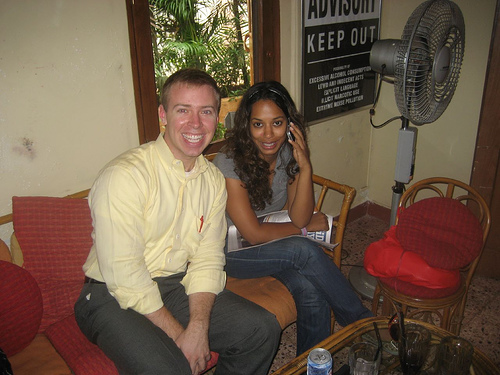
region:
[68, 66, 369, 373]
A man and a woman on a cell phone sitting on bamboo bench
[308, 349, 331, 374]
A can on the table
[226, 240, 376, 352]
The woman is wearing blue pants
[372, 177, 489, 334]
A chair by the couch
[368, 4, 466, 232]
A fan near the chair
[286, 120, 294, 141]
The woman is using a cell phone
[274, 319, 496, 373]
A table near the couch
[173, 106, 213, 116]
The eyes of the man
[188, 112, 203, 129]
The nose of the man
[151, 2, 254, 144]
A window behind the people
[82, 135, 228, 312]
The man is wearing a yellow shirt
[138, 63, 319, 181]
face of the person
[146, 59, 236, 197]
face of the boy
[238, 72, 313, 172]
face of the girl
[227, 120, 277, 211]
curley hairs of the girl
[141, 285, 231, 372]
hand of the man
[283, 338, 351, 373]
a bottle in the table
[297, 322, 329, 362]
a part of bottle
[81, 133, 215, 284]
a man wearing shirt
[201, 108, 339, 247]
a woman wearing shirt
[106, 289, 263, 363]
a man wearing pants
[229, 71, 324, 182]
the girl is holding the phone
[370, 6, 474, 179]
a fan in the corner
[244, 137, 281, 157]
the teeth are showing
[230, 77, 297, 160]
the woman is smiling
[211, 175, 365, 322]
the girl is holding a newspaper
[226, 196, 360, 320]
the girl`s jeans are blue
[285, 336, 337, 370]
a can on the table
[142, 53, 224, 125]
the man has blonde hair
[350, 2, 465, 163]
the fan is grey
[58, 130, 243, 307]
the man`s shirt is yellow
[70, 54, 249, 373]
man sitting on red couch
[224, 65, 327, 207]
girl talking on cell phone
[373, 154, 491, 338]
brown wicker chair with red cushion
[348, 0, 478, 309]
gray fan sitting on floor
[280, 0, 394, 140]
black and white sign hanging on the wall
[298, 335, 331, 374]
aluminium can sitting on table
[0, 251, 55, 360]
red plaid print pillow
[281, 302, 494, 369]
brown wicker table with glass table top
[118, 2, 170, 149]
wooden widnow frame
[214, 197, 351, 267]
newspaper held on someones lap